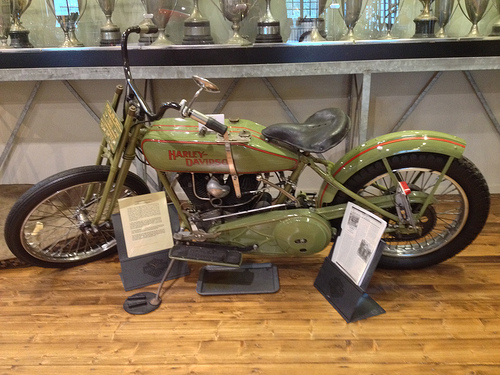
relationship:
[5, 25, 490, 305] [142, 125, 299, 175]
motorcycle has stripe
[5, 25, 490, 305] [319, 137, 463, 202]
motorcycle has stripe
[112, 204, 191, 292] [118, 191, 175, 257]
document holder has paper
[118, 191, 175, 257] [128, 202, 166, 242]
paper has words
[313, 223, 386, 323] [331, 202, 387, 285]
document holder has paper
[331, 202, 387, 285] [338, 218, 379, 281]
paper has words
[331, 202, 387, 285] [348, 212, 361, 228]
paper has photo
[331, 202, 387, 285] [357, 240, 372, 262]
paper has photo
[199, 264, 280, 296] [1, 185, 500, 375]
tray on floor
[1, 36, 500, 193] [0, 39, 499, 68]
table has stripe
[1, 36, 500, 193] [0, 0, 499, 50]
table filled with trophies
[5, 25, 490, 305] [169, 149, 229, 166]
motorcycle has words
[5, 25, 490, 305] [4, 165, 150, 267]
motorcycle has wheel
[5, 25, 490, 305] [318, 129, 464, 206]
motorcycle has fender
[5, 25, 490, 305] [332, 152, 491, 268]
motorcycle has wheel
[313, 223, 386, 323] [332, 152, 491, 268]
document holder in front of wheel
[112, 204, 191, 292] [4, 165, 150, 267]
document holder next to wheel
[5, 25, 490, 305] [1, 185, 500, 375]
motorcycle on floor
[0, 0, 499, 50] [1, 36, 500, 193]
trophies are on table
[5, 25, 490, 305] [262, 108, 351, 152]
motorcycle has seat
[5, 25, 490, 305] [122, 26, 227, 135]
motorcycle has handle bars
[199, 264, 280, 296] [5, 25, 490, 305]
tray below motorcycle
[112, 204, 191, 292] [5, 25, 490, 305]
document holder in front of motorcycle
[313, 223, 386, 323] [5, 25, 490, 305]
document holder in front of motorcycle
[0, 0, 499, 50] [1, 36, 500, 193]
trophies displayed on table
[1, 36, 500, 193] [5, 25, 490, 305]
table behind motorcycle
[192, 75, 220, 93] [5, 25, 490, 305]
mirror on motorcycle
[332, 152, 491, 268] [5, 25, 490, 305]
wheel on motorcycle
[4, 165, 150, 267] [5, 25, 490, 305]
wheel on motorcycle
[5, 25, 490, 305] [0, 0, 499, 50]
motorcycle in front of trophies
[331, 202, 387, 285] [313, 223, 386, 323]
paper on document holder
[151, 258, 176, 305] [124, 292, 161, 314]
kickstand on mat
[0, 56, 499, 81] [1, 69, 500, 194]
bar on wall